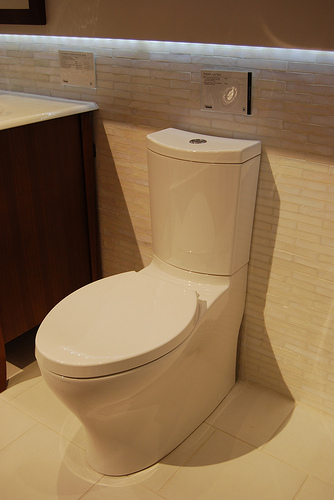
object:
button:
[188, 137, 208, 145]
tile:
[78, 475, 166, 499]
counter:
[0, 59, 99, 130]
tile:
[0, 399, 37, 449]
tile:
[9, 423, 85, 471]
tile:
[0, 361, 42, 403]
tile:
[156, 428, 307, 500]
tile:
[261, 404, 334, 485]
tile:
[9, 377, 88, 451]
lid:
[145, 126, 261, 165]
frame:
[0, 2, 47, 24]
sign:
[203, 72, 247, 115]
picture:
[1, 1, 32, 11]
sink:
[114, 126, 262, 290]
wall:
[263, 1, 334, 413]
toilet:
[31, 124, 262, 474]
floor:
[185, 395, 333, 500]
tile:
[206, 380, 296, 450]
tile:
[291, 474, 333, 499]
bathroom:
[0, 1, 333, 499]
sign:
[61, 49, 96, 87]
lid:
[35, 270, 200, 378]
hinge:
[138, 270, 200, 299]